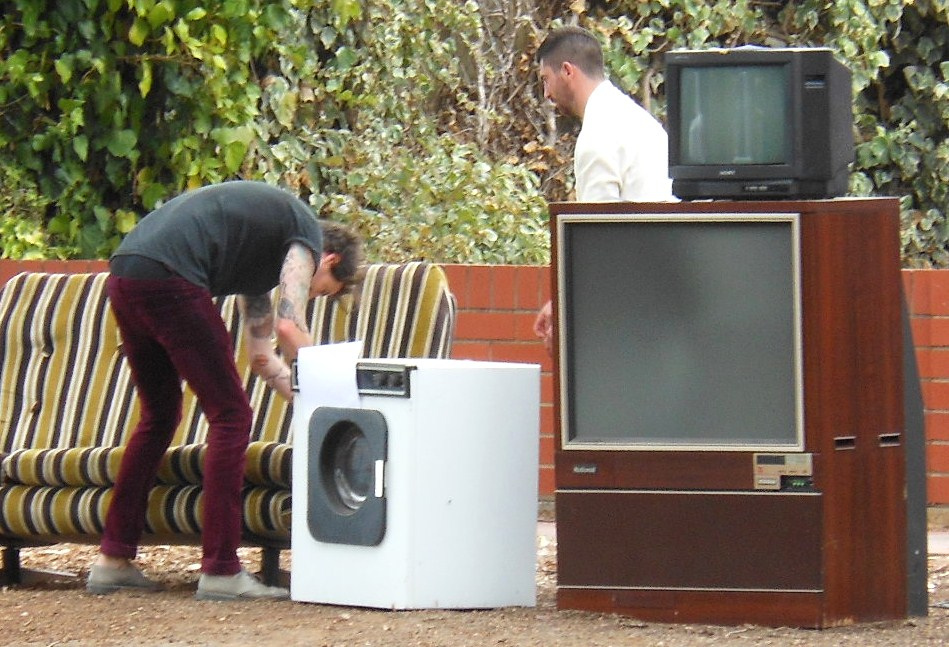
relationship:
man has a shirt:
[499, 15, 673, 154] [556, 84, 662, 247]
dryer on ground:
[289, 341, 540, 611] [221, 579, 447, 637]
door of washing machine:
[293, 390, 403, 564] [278, 333, 543, 636]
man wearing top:
[529, 24, 682, 339] [554, 79, 729, 242]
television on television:
[657, 41, 858, 201] [544, 196, 933, 625]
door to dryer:
[310, 406, 387, 546] [292, 353, 543, 618]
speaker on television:
[554, 484, 842, 597] [546, 201, 910, 625]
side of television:
[809, 205, 912, 631] [546, 201, 910, 625]